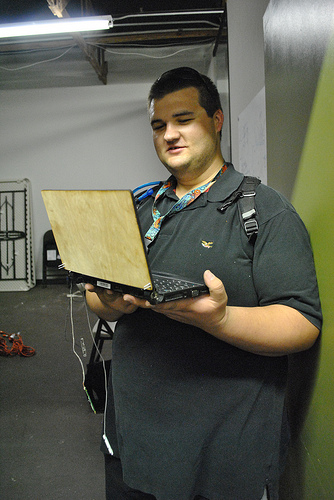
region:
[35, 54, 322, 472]
a man holding a laptop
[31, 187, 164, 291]
a laptop with a wooden LCD screen back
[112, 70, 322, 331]
a man wearing a black shirt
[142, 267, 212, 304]
the keyboard of a laptop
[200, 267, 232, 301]
the thumb of a man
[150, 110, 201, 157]
the face of a man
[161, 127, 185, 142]
the nose of a man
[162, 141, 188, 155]
the mouth of a man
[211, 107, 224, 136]
the ear of a man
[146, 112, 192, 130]
the eyes of a man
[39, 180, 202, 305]
laptop computer with a wooden back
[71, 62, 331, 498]
guy in a black polo shirt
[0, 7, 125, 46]
overhead flourescent light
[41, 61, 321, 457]
guy holding a laptop computer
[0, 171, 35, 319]
folding tables against a wall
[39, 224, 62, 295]
black folding chair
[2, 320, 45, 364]
orange extension cord on the ground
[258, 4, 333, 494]
olive green wall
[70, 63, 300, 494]
guy wearing a colorful lanyard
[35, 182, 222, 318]
black and wood laptop computer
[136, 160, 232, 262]
blue and orange strap around neck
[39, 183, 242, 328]
man holding laptop in both hands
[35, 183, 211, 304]
black and wood-colored laptop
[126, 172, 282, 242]
black straps on shoulders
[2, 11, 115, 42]
horizontal white light on ceiling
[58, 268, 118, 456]
white cords hanging from laptop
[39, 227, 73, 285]
black folding chair against wall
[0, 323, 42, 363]
orange and black strap on floor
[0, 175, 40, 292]
white table with black legs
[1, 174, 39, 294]
folding table against wall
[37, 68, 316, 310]
A man looks at the computer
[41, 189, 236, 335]
A person holds a computer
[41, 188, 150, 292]
Back of the laptop is tan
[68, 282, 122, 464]
White wires hang down from a computer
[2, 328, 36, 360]
A clump of orange cords on the floor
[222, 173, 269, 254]
A backpack strap on a shoulder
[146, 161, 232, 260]
A multicolored strap around man's neck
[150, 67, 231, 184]
Sunglasses on a man's head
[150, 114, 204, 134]
The man is squinting his eyes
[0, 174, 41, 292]
White tables stacked against the wall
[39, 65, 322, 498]
a alrge guy holding a small laptop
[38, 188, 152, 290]
a wood grain decal on laptop lid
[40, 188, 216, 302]
a small black laptop with wood decal lid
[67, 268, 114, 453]
a dangling white cord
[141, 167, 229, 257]
a multi-colored lanyard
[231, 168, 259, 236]
a bookbag strap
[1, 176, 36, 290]
white palstice folding tables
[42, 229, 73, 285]
dark metal folding chairs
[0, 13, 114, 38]
a set of fluorescent lights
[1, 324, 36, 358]
orange object on floor